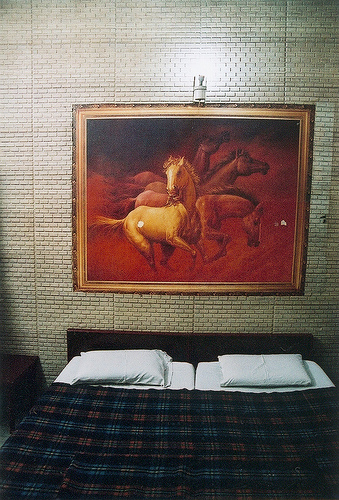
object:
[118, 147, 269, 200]
horse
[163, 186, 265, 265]
horse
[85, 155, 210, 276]
horse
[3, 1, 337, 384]
wall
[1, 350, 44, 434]
brown table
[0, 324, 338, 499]
bed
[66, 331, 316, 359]
brown headboard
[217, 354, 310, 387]
white pillow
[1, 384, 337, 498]
plaid bedspread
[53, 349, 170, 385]
white pillow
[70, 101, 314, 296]
painting